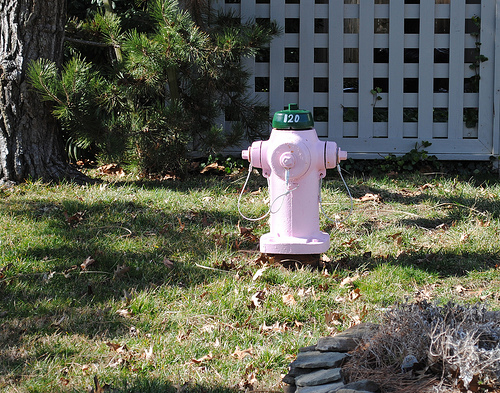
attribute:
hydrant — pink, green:
[236, 99, 354, 267]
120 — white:
[281, 110, 303, 126]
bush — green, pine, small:
[24, 1, 273, 190]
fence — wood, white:
[207, 6, 499, 169]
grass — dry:
[4, 165, 498, 383]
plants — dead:
[220, 260, 359, 327]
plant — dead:
[353, 290, 490, 380]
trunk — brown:
[4, 2, 79, 180]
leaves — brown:
[358, 189, 383, 204]